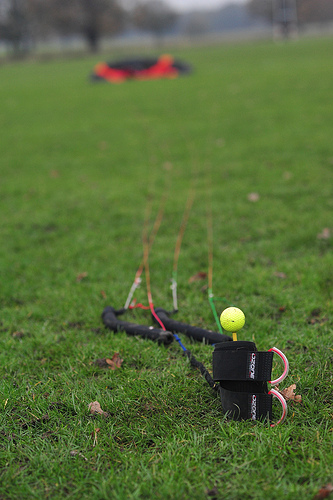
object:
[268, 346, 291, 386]
red/white handles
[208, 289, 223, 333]
green strap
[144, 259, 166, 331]
red strap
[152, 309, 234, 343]
black/thick chord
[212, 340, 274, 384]
black cuff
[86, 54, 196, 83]
kite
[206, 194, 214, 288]
string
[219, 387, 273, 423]
cloth harness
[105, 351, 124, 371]
dead leaf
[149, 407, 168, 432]
short tuft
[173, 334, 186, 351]
line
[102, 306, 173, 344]
strap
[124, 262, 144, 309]
rope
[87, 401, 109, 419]
leaves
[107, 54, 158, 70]
focus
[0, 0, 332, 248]
background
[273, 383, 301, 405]
leaf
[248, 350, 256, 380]
brand name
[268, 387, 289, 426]
stirrups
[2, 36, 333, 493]
grass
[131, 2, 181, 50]
trees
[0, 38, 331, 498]
field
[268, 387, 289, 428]
grip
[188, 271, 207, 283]
leaf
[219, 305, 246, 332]
ball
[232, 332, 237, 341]
stick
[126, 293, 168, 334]
object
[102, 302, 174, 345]
handle